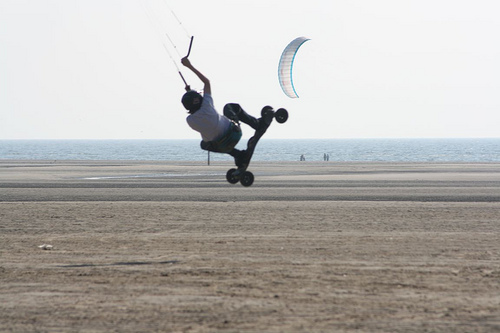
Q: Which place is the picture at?
A: It is at the beach.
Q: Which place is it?
A: It is a beach.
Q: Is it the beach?
A: Yes, it is the beach.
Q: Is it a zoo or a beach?
A: It is a beach.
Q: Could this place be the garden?
A: No, it is the beach.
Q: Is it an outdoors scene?
A: Yes, it is outdoors.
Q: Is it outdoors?
A: Yes, it is outdoors.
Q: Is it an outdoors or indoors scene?
A: It is outdoors.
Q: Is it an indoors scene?
A: No, it is outdoors.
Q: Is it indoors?
A: No, it is outdoors.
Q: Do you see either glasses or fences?
A: No, there are no fences or glasses.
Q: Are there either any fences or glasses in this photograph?
A: No, there are no fences or glasses.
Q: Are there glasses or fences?
A: No, there are no fences or glasses.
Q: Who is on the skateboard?
A: The man is on the skateboard.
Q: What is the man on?
A: The man is on the skateboard.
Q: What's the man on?
A: The man is on the skateboard.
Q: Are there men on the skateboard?
A: Yes, there is a man on the skateboard.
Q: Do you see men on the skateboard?
A: Yes, there is a man on the skateboard.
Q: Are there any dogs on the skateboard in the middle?
A: No, there is a man on the skateboard.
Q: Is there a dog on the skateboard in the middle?
A: No, there is a man on the skateboard.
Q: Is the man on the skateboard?
A: Yes, the man is on the skateboard.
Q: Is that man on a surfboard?
A: No, the man is on the skateboard.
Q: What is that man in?
A: The man is in the air.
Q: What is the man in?
A: The man is in the air.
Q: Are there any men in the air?
A: Yes, there is a man in the air.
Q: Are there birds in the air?
A: No, there is a man in the air.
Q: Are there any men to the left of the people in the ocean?
A: Yes, there is a man to the left of the people.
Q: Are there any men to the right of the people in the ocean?
A: No, the man is to the left of the people.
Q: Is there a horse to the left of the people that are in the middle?
A: No, there is a man to the left of the people.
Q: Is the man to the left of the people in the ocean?
A: Yes, the man is to the left of the people.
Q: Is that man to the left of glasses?
A: No, the man is to the left of the people.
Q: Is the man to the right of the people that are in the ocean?
A: No, the man is to the left of the people.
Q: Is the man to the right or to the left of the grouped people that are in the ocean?
A: The man is to the left of the people.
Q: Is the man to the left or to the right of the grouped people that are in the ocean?
A: The man is to the left of the people.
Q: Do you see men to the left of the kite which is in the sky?
A: Yes, there is a man to the left of the kite.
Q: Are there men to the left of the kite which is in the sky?
A: Yes, there is a man to the left of the kite.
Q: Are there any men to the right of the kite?
A: No, the man is to the left of the kite.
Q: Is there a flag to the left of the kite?
A: No, there is a man to the left of the kite.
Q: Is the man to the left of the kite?
A: Yes, the man is to the left of the kite.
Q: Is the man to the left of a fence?
A: No, the man is to the left of the kite.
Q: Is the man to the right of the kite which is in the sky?
A: No, the man is to the left of the kite.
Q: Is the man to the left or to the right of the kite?
A: The man is to the left of the kite.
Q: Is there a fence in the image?
A: No, there are no fences.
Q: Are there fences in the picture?
A: No, there are no fences.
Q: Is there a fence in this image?
A: No, there are no fences.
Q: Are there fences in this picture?
A: No, there are no fences.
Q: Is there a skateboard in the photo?
A: Yes, there is a skateboard.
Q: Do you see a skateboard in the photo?
A: Yes, there is a skateboard.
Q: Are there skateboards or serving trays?
A: Yes, there is a skateboard.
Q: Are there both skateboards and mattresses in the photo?
A: No, there is a skateboard but no mattresses.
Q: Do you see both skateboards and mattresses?
A: No, there is a skateboard but no mattresses.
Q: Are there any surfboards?
A: No, there are no surfboards.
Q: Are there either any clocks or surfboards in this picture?
A: No, there are no surfboards or clocks.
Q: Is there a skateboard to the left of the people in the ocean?
A: Yes, there is a skateboard to the left of the people.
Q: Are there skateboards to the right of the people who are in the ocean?
A: No, the skateboard is to the left of the people.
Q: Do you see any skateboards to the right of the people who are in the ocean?
A: No, the skateboard is to the left of the people.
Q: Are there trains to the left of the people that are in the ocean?
A: No, there is a skateboard to the left of the people.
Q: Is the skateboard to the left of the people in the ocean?
A: Yes, the skateboard is to the left of the people.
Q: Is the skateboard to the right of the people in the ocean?
A: No, the skateboard is to the left of the people.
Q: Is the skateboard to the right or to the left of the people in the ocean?
A: The skateboard is to the left of the people.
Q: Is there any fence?
A: No, there are no fences.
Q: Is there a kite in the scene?
A: Yes, there is a kite.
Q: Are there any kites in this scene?
A: Yes, there is a kite.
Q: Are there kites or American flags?
A: Yes, there is a kite.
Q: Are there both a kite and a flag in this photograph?
A: No, there is a kite but no flags.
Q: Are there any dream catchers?
A: No, there are no dream catchers.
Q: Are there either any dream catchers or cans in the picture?
A: No, there are no dream catchers or cans.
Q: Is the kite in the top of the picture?
A: Yes, the kite is in the top of the image.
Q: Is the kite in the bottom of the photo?
A: No, the kite is in the top of the image.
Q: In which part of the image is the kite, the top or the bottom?
A: The kite is in the top of the image.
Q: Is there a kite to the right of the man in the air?
A: Yes, there is a kite to the right of the man.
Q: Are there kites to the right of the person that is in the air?
A: Yes, there is a kite to the right of the man.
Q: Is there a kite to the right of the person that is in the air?
A: Yes, there is a kite to the right of the man.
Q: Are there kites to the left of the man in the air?
A: No, the kite is to the right of the man.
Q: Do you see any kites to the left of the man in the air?
A: No, the kite is to the right of the man.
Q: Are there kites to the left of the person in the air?
A: No, the kite is to the right of the man.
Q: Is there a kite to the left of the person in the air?
A: No, the kite is to the right of the man.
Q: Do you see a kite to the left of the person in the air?
A: No, the kite is to the right of the man.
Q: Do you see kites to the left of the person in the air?
A: No, the kite is to the right of the man.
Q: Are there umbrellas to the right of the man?
A: No, there is a kite to the right of the man.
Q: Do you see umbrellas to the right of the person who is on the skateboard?
A: No, there is a kite to the right of the man.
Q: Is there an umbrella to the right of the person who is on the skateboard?
A: No, there is a kite to the right of the man.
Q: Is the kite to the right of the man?
A: Yes, the kite is to the right of the man.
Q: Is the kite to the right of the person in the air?
A: Yes, the kite is to the right of the man.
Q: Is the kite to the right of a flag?
A: No, the kite is to the right of the man.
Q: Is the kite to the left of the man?
A: No, the kite is to the right of the man.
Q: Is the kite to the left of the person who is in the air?
A: No, the kite is to the right of the man.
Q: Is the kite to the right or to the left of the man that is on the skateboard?
A: The kite is to the right of the man.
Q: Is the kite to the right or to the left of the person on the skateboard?
A: The kite is to the right of the man.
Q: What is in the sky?
A: The kite is in the sky.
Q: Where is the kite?
A: The kite is in the sky.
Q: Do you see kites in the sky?
A: Yes, there is a kite in the sky.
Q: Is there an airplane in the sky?
A: No, there is a kite in the sky.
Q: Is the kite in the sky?
A: Yes, the kite is in the sky.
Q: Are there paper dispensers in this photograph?
A: No, there are no paper dispensers.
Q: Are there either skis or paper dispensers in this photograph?
A: No, there are no paper dispensers or skis.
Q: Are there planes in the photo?
A: No, there are no planes.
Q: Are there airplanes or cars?
A: No, there are no airplanes or cars.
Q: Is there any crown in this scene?
A: No, there are no crowns.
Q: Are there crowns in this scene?
A: No, there are no crowns.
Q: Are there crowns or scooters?
A: No, there are no crowns or scooters.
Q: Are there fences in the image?
A: No, there are no fences.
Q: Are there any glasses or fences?
A: No, there are no fences or glasses.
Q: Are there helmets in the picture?
A: Yes, there is a helmet.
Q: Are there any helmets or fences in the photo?
A: Yes, there is a helmet.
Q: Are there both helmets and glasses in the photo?
A: No, there is a helmet but no glasses.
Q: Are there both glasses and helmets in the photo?
A: No, there is a helmet but no glasses.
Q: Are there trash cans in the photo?
A: No, there are no trash cans.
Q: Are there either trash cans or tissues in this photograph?
A: No, there are no trash cans or tissues.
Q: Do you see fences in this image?
A: No, there are no fences.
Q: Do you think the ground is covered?
A: Yes, the ground is covered.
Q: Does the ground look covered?
A: Yes, the ground is covered.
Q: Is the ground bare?
A: No, the ground is covered.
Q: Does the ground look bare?
A: No, the ground is covered.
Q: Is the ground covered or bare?
A: The ground is covered.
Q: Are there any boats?
A: No, there are no boats.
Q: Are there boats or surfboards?
A: No, there are no boats or surfboards.